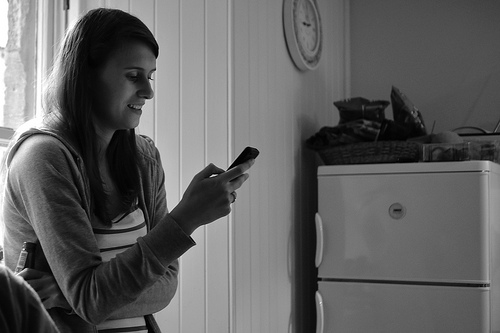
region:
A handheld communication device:
[201, 140, 272, 206]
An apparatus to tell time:
[275, 0, 337, 76]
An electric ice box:
[312, 160, 499, 310]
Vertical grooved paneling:
[168, 1, 225, 115]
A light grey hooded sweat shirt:
[4, 117, 199, 327]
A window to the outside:
[0, 1, 82, 254]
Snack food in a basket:
[313, 86, 433, 157]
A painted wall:
[379, 21, 472, 75]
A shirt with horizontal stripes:
[87, 198, 154, 331]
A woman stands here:
[41, 7, 176, 188]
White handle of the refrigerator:
[313, 296, 327, 331]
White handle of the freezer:
[311, 214, 328, 269]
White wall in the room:
[419, 21, 454, 56]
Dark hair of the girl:
[79, 24, 95, 90]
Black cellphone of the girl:
[230, 144, 257, 160]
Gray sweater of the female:
[31, 152, 71, 244]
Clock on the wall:
[286, 0, 323, 64]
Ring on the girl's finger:
[231, 192, 239, 204]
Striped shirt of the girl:
[95, 226, 135, 252]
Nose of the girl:
[141, 86, 153, 97]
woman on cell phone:
[9, 5, 273, 328]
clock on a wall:
[267, 3, 342, 75]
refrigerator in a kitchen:
[306, 158, 497, 327]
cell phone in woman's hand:
[225, 139, 260, 176]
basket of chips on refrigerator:
[311, 85, 431, 167]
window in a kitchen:
[8, 2, 48, 139]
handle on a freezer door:
[308, 211, 329, 275]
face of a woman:
[97, 43, 165, 133]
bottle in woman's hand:
[14, 231, 44, 278]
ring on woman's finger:
[227, 187, 241, 209]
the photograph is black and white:
[18, 6, 493, 326]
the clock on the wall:
[271, 5, 333, 67]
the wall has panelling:
[243, 6, 347, 327]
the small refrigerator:
[313, 149, 498, 331]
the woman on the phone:
[0, 10, 267, 331]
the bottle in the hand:
[1, 235, 49, 297]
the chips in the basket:
[309, 90, 434, 162]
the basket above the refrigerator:
[315, 82, 439, 174]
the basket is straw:
[307, 114, 433, 166]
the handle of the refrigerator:
[303, 287, 340, 331]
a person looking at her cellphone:
[3, 7, 256, 326]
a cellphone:
[221, 137, 258, 180]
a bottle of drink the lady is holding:
[6, 235, 38, 284]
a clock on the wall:
[278, 0, 340, 70]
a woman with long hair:
[7, 2, 180, 269]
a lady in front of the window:
[3, 2, 186, 332]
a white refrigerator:
[287, 107, 497, 324]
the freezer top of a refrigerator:
[294, 155, 496, 299]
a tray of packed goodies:
[299, 65, 424, 175]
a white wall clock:
[279, 2, 333, 87]